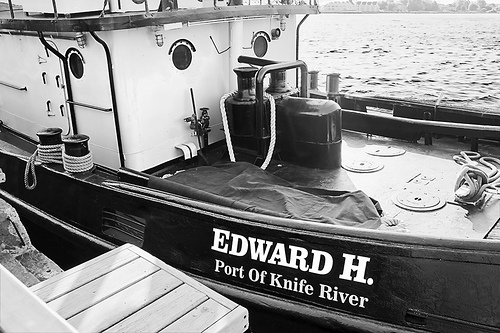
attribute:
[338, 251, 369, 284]
letter — written, white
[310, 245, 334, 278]
letter — written, white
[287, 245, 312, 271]
r — white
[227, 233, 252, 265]
d — written, white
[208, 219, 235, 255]
e — written, white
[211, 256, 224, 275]
p — white, written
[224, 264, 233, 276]
o — white, written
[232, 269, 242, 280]
r — white, written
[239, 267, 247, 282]
t — white, written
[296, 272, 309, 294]
letter — written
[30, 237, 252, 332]
stone — white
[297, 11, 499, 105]
river — flowing, wavy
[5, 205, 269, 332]
dock — wooden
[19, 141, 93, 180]
rope — wrapped, windy, big, white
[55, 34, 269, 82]
portholes — dark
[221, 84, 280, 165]
rope — thick